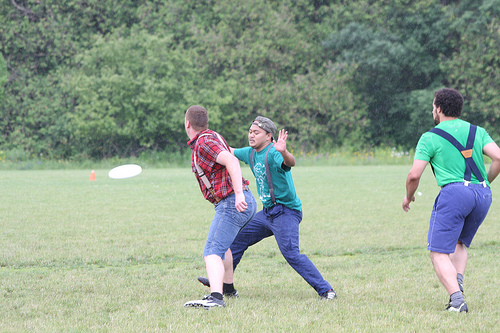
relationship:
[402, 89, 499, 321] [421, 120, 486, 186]
man wearing suspenders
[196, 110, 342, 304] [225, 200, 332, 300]
man wearing jeans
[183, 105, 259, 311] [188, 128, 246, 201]
man wearing plaid shirt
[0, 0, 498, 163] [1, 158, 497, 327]
trees are at edge of field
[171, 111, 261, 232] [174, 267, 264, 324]
man wearing shoes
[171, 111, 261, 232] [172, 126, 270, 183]
man wearing shirt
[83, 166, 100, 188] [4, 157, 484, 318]
cone in grass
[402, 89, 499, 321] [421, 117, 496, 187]
man wearing suspenders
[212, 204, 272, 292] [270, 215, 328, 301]
leg apart from leg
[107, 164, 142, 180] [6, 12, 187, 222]
disc in air